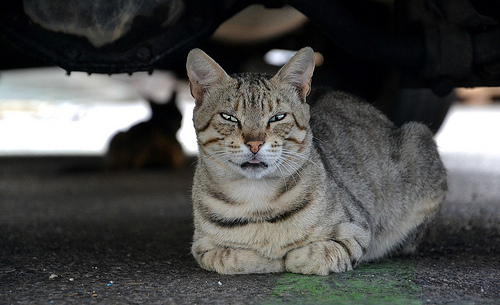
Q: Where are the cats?
A: Under a vehicle.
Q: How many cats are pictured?
A: Two.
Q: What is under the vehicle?
A: Cats.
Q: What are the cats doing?
A: Lying down.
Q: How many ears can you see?
A: Four.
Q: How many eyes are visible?
A: Two.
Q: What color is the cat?
A: Grey with stripes.